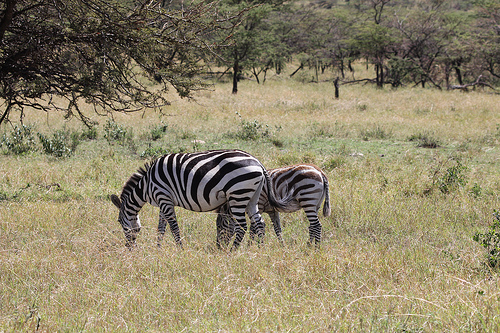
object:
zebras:
[106, 149, 286, 249]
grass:
[0, 59, 499, 332]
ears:
[110, 195, 126, 212]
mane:
[113, 160, 165, 201]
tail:
[323, 176, 332, 215]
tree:
[0, 0, 263, 118]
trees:
[163, 0, 278, 95]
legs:
[152, 201, 183, 252]